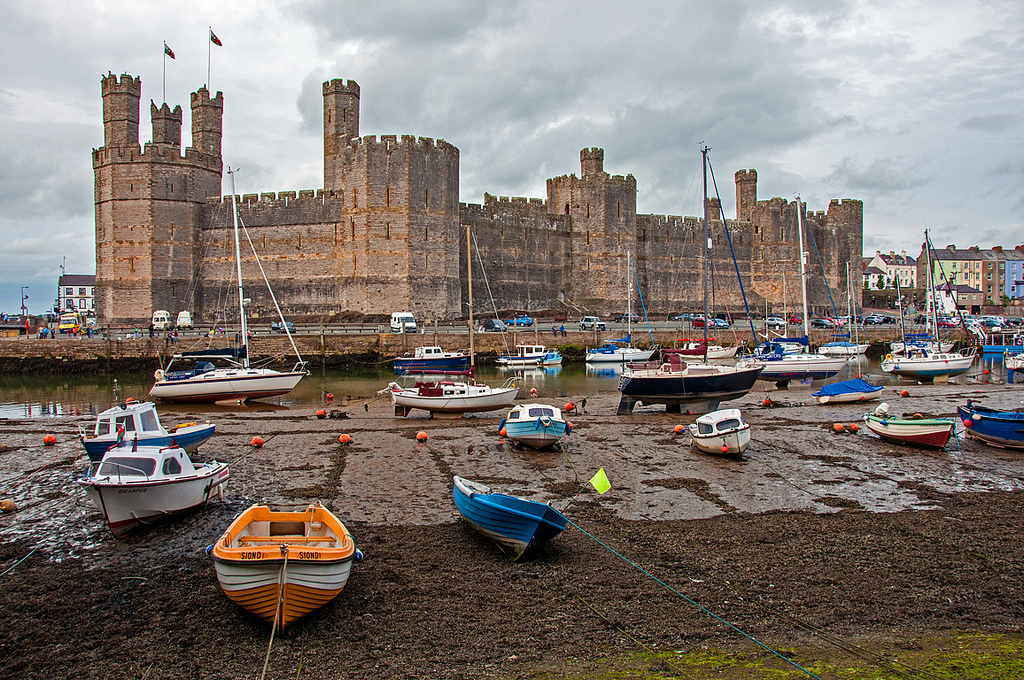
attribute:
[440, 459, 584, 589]
boat — blue 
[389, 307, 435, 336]
van — white 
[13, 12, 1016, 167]
clouds — white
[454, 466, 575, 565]
blue boat — small 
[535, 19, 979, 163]
clouds — white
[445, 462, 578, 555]
boat — blue 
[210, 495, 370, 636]
boat — white, orange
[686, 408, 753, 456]
boat — small , white 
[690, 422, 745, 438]
stripe — red 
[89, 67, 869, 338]
building — brick, large